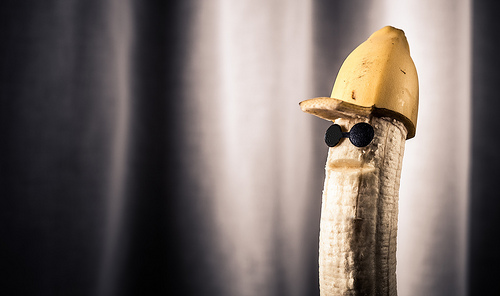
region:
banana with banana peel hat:
[301, 25, 417, 291]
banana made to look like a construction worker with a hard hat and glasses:
[298, 21, 423, 293]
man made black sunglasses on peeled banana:
[316, 117, 376, 147]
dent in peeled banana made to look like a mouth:
[321, 150, 381, 180]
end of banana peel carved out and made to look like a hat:
[301, 15, 416, 135]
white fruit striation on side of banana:
[342, 181, 392, 276]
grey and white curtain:
[5, 1, 260, 291]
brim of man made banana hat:
[290, 95, 360, 115]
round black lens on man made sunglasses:
[346, 121, 372, 142]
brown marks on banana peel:
[345, 60, 376, 97]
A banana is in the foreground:
[290, 13, 436, 293]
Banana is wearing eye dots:
[315, 117, 380, 152]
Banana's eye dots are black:
[315, 108, 380, 160]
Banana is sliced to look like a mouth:
[318, 151, 383, 183]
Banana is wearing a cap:
[288, 16, 431, 144]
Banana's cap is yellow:
[287, 14, 454, 142]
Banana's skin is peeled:
[308, 117, 425, 294]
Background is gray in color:
[3, 23, 494, 276]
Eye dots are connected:
[318, 119, 388, 153]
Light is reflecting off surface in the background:
[187, 1, 462, 293]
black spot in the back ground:
[138, 82, 164, 137]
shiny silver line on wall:
[93, 82, 137, 168]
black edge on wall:
[453, 66, 492, 151]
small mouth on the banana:
[295, 144, 377, 177]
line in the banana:
[368, 224, 405, 274]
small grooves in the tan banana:
[315, 172, 400, 222]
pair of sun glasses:
[287, 113, 391, 152]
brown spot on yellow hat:
[338, 89, 365, 98]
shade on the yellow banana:
[279, 79, 386, 128]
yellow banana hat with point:
[345, 21, 441, 101]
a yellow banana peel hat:
[300, 25, 425, 133]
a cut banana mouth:
[321, 155, 376, 175]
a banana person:
[300, 25, 420, 290]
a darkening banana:
[311, 115, 398, 290]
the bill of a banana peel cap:
[300, 85, 375, 111]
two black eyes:
[315, 115, 370, 145]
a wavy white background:
[4, 3, 497, 294]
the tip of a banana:
[373, 24, 413, 48]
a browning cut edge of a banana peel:
[332, 97, 419, 132]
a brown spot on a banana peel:
[349, 88, 358, 103]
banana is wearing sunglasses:
[320, 118, 376, 150]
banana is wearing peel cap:
[295, 22, 419, 136]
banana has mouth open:
[314, 153, 381, 178]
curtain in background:
[2, 1, 302, 290]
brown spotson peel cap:
[344, 54, 376, 102]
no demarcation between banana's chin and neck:
[317, 179, 376, 294]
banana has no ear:
[381, 121, 413, 161]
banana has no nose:
[334, 133, 359, 157]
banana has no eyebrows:
[327, 115, 379, 126]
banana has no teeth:
[322, 154, 374, 178]